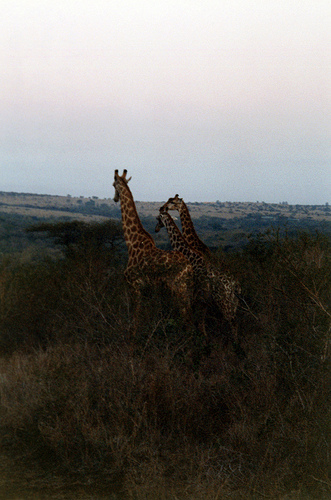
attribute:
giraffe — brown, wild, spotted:
[111, 170, 197, 353]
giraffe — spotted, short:
[152, 207, 260, 351]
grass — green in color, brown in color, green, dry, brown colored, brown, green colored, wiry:
[0, 238, 330, 496]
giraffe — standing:
[160, 191, 210, 253]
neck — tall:
[117, 189, 154, 258]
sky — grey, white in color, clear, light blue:
[4, 0, 329, 208]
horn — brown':
[114, 169, 122, 183]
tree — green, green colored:
[32, 221, 145, 255]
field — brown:
[4, 190, 330, 235]